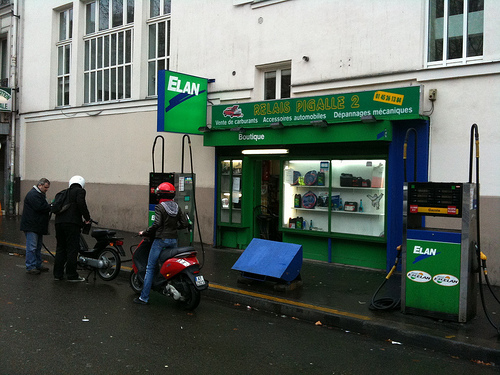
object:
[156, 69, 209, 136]
sign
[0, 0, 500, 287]
building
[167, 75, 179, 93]
lettering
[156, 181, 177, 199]
helmet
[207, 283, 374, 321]
line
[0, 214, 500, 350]
sidewalk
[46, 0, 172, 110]
window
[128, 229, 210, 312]
motorcycle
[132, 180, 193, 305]
person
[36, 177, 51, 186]
hair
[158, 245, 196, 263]
seat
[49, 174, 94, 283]
men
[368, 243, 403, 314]
pump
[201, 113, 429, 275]
shop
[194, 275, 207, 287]
plate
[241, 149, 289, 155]
light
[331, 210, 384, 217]
shelves